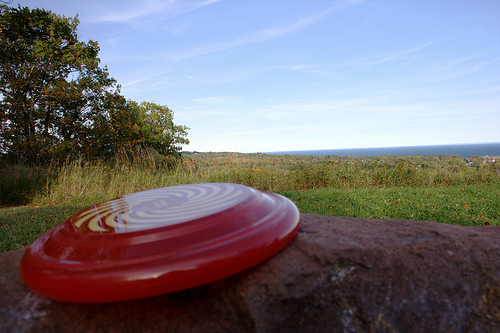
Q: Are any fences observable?
A: No, there are no fences.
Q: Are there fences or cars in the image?
A: No, there are no fences or cars.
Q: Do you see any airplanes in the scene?
A: No, there are no airplanes.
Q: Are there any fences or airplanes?
A: No, there are no airplanes or fences.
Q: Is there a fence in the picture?
A: No, there are no fences.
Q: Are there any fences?
A: No, there are no fences.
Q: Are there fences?
A: No, there are no fences.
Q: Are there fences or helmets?
A: No, there are no fences or helmets.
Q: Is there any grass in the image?
A: Yes, there is grass.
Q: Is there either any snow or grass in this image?
A: Yes, there is grass.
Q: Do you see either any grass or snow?
A: Yes, there is grass.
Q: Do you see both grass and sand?
A: No, there is grass but no sand.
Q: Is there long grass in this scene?
A: Yes, there is long grass.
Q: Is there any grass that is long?
A: Yes, there is grass that is long.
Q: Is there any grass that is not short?
A: Yes, there is long grass.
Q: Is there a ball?
A: No, there are no balls.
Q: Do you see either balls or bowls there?
A: No, there are no balls or bowls.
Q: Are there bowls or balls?
A: No, there are no balls or bowls.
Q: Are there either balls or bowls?
A: No, there are no balls or bowls.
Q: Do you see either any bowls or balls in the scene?
A: No, there are no balls or bowls.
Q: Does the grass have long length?
A: Yes, the grass is long.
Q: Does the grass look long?
A: Yes, the grass is long.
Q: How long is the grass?
A: The grass is long.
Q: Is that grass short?
A: No, the grass is long.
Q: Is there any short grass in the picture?
A: No, there is grass but it is long.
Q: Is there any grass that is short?
A: No, there is grass but it is long.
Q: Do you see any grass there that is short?
A: No, there is grass but it is long.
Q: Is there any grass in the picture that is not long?
A: No, there is grass but it is long.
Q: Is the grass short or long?
A: The grass is long.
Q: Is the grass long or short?
A: The grass is long.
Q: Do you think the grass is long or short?
A: The grass is long.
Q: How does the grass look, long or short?
A: The grass is long.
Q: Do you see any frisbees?
A: Yes, there is a frisbee.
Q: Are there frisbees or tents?
A: Yes, there is a frisbee.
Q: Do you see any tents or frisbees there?
A: Yes, there is a frisbee.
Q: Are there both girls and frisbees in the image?
A: No, there is a frisbee but no girls.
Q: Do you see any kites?
A: No, there are no kites.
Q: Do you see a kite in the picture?
A: No, there are no kites.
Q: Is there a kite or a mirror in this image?
A: No, there are no kites or mirrors.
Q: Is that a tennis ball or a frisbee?
A: That is a frisbee.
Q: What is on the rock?
A: The frisbee is on the rock.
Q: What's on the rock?
A: The frisbee is on the rock.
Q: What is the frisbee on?
A: The frisbee is on the rock.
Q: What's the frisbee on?
A: The frisbee is on the rock.